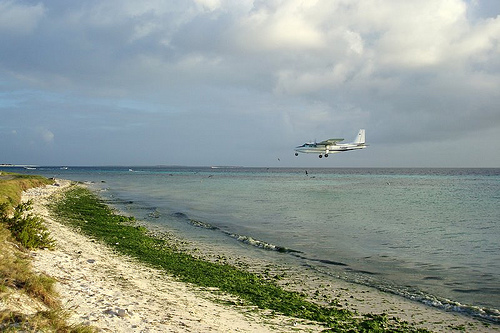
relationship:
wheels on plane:
[317, 152, 330, 159] [296, 129, 368, 158]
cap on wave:
[246, 236, 257, 243] [222, 231, 301, 258]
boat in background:
[211, 166, 219, 171] [1, 0, 499, 171]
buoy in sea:
[384, 180, 395, 189] [4, 165, 499, 326]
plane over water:
[296, 129, 368, 158] [4, 165, 499, 326]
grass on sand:
[4, 172, 55, 323] [21, 177, 325, 327]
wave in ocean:
[222, 231, 301, 258] [49, 181, 404, 331]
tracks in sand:
[45, 240, 209, 333] [21, 177, 325, 327]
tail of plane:
[357, 130, 367, 150] [296, 129, 368, 158]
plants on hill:
[6, 195, 49, 260] [5, 176, 39, 324]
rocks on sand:
[267, 263, 340, 306] [21, 177, 325, 327]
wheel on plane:
[293, 152, 303, 158] [296, 129, 368, 158]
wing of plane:
[323, 138, 344, 148] [296, 129, 368, 158]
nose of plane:
[295, 145, 300, 154] [296, 129, 368, 158]